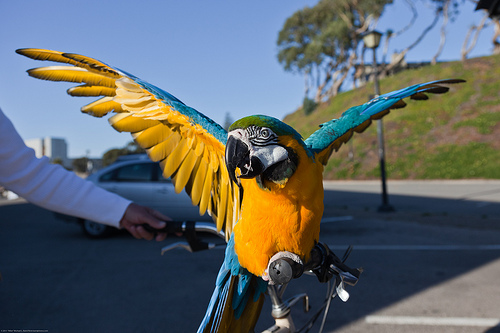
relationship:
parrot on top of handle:
[19, 40, 466, 332] [267, 243, 338, 286]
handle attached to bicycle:
[267, 243, 338, 286] [224, 269, 396, 332]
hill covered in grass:
[379, 61, 498, 174] [433, 143, 496, 171]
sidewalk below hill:
[396, 178, 500, 211] [379, 61, 498, 174]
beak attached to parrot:
[222, 132, 250, 184] [19, 40, 466, 332]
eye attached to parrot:
[249, 123, 277, 142] [19, 40, 466, 332]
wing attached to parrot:
[304, 77, 468, 160] [19, 40, 466, 332]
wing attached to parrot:
[20, 46, 229, 223] [19, 40, 466, 332]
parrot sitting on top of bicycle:
[19, 40, 466, 332] [224, 269, 396, 332]